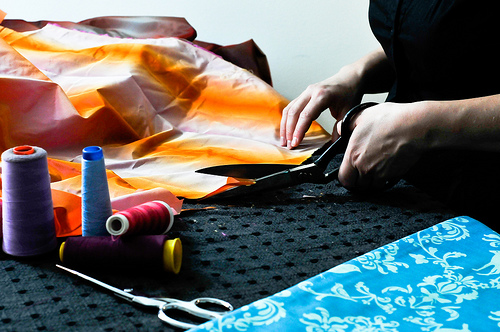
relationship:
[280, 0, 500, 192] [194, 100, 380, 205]
woman holding scissors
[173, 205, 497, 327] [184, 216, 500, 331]
edge of blue cloth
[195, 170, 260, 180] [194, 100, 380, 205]
edge lining scissors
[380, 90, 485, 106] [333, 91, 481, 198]
edge lining arm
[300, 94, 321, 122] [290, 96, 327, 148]
part belonging to finger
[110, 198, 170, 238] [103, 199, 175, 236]
thread wrapped around spool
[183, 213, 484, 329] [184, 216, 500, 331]
pattern adorning blue cloth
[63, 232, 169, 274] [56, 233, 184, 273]
thread wrapped around spool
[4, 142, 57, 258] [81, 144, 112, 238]
thread wrapped around spool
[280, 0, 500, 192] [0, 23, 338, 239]
woman cutting material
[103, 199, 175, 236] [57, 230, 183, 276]
spool lying on top of spool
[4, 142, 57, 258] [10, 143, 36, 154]
thread wrapped around spool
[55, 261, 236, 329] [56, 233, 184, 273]
scissors lying next to spool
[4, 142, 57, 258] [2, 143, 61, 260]
thread wrapped around spool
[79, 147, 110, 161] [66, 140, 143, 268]
spool of blue thread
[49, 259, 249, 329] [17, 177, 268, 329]
scissors laying on cloth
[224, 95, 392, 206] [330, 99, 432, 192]
scissors in woman's hand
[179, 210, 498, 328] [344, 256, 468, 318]
blue cloth with white design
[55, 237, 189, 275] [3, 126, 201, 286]
spool of thread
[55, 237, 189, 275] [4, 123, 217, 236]
spool of thread on cloth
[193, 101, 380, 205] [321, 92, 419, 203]
scissors with black handle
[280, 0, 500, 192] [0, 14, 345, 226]
woman cutting material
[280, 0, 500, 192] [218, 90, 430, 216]
woman cutting material with scissors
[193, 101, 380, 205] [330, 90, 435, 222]
scissors in woman's hand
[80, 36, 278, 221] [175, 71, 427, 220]
material being cut by scissors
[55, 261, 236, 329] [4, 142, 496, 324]
scissors lying on work table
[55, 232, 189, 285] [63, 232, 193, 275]
spool of thread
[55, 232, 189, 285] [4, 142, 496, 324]
spool lying on work table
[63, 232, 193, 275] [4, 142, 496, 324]
thread lying on work table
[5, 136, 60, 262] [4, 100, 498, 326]
spool sitting on work table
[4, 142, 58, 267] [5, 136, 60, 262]
thread sitting on spool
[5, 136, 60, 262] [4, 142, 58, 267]
spool of thread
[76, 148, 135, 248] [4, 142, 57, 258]
spool of thread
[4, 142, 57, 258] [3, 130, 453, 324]
thread sitting on work table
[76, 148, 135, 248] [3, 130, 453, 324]
spool sitting on work table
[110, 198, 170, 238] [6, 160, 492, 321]
thread sitting on work table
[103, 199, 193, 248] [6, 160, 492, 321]
spool sitting on work table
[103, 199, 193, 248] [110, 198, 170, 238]
spool of thread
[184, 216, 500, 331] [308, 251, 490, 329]
blue cloth with flower designs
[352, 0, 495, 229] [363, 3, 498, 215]
woman with black blouse